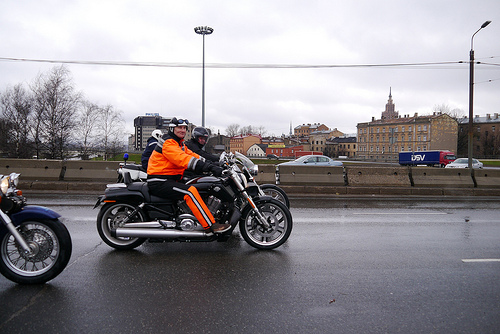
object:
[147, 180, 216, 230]
pants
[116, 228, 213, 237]
pipe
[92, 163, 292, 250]
bike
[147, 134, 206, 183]
jacket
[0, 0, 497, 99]
sky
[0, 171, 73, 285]
front end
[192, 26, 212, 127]
pole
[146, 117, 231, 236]
man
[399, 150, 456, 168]
truck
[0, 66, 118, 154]
tree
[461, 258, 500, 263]
line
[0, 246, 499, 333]
road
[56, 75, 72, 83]
branch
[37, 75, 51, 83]
branch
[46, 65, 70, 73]
branch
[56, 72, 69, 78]
branch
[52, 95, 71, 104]
branch